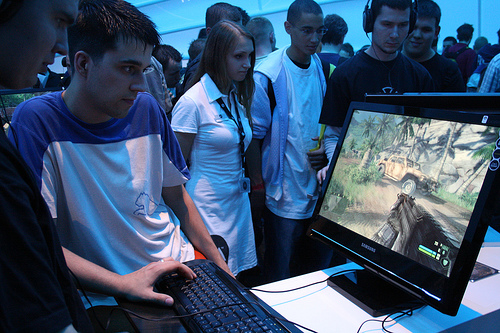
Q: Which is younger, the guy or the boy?
A: The boy is younger than the guy.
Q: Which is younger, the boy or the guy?
A: The boy is younger than the guy.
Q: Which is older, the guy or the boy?
A: The guy is older than the boy.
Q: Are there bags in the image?
A: No, there are no bags.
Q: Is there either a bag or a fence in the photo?
A: No, there are no bags or fences.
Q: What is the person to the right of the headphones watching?
A: The person is watching the computer monitor.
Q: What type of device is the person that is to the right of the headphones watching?
A: The person is watching the computer monitor.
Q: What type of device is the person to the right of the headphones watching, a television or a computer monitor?
A: The person is watching a computer monitor.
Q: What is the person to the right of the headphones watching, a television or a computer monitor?
A: The person is watching a computer monitor.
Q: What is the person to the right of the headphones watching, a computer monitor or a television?
A: The person is watching a computer monitor.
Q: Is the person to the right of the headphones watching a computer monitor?
A: Yes, the person is watching a computer monitor.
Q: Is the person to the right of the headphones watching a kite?
A: No, the person is watching a computer monitor.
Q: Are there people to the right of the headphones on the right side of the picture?
A: Yes, there is a person to the right of the headphones.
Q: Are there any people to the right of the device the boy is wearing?
A: Yes, there is a person to the right of the headphones.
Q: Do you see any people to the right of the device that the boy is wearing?
A: Yes, there is a person to the right of the headphones.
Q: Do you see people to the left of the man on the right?
A: Yes, there is a person to the left of the man.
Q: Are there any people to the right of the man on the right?
A: No, the person is to the left of the man.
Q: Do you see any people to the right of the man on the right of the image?
A: No, the person is to the left of the man.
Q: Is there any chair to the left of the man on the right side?
A: No, there is a person to the left of the man.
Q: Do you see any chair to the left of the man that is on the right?
A: No, there is a person to the left of the man.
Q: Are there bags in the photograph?
A: No, there are no bags.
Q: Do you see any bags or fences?
A: No, there are no bags or fences.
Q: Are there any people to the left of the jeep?
A: Yes, there are people to the left of the jeep.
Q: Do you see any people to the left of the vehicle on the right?
A: Yes, there are people to the left of the jeep.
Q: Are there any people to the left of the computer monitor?
A: Yes, there are people to the left of the computer monitor.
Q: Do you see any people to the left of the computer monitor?
A: Yes, there are people to the left of the computer monitor.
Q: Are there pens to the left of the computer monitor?
A: No, there are people to the left of the computer monitor.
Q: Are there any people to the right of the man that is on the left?
A: Yes, there are people to the right of the man.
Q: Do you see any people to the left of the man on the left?
A: No, the people are to the right of the man.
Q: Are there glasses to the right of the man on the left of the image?
A: No, there are people to the right of the man.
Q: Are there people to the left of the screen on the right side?
A: Yes, there are people to the left of the screen.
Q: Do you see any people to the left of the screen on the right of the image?
A: Yes, there are people to the left of the screen.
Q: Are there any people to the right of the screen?
A: No, the people are to the left of the screen.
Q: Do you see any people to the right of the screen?
A: No, the people are to the left of the screen.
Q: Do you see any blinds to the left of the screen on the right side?
A: No, there are people to the left of the screen.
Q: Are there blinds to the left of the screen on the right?
A: No, there are people to the left of the screen.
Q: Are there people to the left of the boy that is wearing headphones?
A: Yes, there are people to the left of the boy.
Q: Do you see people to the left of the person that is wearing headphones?
A: Yes, there are people to the left of the boy.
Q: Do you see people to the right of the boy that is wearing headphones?
A: No, the people are to the left of the boy.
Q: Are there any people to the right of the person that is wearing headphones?
A: No, the people are to the left of the boy.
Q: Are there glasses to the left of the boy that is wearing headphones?
A: No, there are people to the left of the boy.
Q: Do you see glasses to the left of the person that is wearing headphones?
A: No, there are people to the left of the boy.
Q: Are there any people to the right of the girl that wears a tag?
A: Yes, there are people to the right of the girl.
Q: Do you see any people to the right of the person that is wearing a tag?
A: Yes, there are people to the right of the girl.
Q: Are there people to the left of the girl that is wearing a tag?
A: No, the people are to the right of the girl.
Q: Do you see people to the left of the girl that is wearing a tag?
A: No, the people are to the right of the girl.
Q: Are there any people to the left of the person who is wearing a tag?
A: No, the people are to the right of the girl.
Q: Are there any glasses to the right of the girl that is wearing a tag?
A: No, there are people to the right of the girl.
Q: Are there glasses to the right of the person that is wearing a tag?
A: No, there are people to the right of the girl.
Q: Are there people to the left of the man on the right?
A: Yes, there are people to the left of the man.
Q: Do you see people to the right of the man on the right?
A: No, the people are to the left of the man.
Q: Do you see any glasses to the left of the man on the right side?
A: No, there are people to the left of the man.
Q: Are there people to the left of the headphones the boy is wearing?
A: Yes, there are people to the left of the headphones.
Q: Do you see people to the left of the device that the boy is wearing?
A: Yes, there are people to the left of the headphones.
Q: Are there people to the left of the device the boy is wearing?
A: Yes, there are people to the left of the headphones.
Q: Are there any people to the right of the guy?
A: Yes, there are people to the right of the guy.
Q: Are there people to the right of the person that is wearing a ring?
A: Yes, there are people to the right of the guy.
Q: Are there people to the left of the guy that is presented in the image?
A: No, the people are to the right of the guy.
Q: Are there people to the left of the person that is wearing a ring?
A: No, the people are to the right of the guy.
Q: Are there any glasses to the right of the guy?
A: No, there are people to the right of the guy.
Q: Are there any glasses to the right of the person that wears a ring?
A: No, there are people to the right of the guy.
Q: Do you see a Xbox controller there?
A: No, there are no Xbox controllers.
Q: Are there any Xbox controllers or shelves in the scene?
A: No, there are no Xbox controllers or shelves.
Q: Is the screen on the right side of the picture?
A: Yes, the screen is on the right of the image.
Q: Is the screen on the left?
A: No, the screen is on the right of the image.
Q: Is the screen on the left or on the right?
A: The screen is on the right of the image.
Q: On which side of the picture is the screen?
A: The screen is on the right of the image.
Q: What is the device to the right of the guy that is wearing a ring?
A: The device is a screen.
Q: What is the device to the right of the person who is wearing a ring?
A: The device is a screen.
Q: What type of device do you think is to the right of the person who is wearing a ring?
A: The device is a screen.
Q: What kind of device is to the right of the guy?
A: The device is a screen.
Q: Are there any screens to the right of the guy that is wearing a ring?
A: Yes, there is a screen to the right of the guy.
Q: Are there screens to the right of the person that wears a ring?
A: Yes, there is a screen to the right of the guy.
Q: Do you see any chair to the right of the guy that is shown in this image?
A: No, there is a screen to the right of the guy.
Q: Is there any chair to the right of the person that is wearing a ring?
A: No, there is a screen to the right of the guy.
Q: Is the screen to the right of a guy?
A: Yes, the screen is to the right of a guy.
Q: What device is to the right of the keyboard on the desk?
A: The device is a screen.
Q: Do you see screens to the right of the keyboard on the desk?
A: Yes, there is a screen to the right of the keyboard.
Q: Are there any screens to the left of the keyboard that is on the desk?
A: No, the screen is to the right of the keyboard.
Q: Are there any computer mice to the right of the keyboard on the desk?
A: No, there is a screen to the right of the keyboard.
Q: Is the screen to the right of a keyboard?
A: Yes, the screen is to the right of a keyboard.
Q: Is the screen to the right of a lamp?
A: No, the screen is to the right of a keyboard.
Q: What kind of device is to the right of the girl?
A: The device is a screen.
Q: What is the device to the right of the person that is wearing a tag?
A: The device is a screen.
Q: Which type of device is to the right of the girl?
A: The device is a screen.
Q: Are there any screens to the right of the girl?
A: Yes, there is a screen to the right of the girl.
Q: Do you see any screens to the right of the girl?
A: Yes, there is a screen to the right of the girl.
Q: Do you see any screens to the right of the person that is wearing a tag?
A: Yes, there is a screen to the right of the girl.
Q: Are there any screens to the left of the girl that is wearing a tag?
A: No, the screen is to the right of the girl.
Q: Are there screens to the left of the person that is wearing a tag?
A: No, the screen is to the right of the girl.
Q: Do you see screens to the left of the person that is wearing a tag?
A: No, the screen is to the right of the girl.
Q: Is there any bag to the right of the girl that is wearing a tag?
A: No, there is a screen to the right of the girl.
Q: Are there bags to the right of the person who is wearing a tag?
A: No, there is a screen to the right of the girl.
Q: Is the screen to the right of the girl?
A: Yes, the screen is to the right of the girl.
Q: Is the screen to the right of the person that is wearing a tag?
A: Yes, the screen is to the right of the girl.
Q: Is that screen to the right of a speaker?
A: No, the screen is to the right of the girl.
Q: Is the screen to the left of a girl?
A: No, the screen is to the right of a girl.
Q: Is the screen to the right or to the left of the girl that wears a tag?
A: The screen is to the right of the girl.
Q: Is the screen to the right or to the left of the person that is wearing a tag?
A: The screen is to the right of the girl.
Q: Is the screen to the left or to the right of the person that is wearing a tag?
A: The screen is to the right of the girl.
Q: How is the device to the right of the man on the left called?
A: The device is a screen.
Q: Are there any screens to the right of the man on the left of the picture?
A: Yes, there is a screen to the right of the man.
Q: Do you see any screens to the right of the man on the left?
A: Yes, there is a screen to the right of the man.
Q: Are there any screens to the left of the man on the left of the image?
A: No, the screen is to the right of the man.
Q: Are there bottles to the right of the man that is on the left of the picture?
A: No, there is a screen to the right of the man.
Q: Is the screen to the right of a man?
A: Yes, the screen is to the right of a man.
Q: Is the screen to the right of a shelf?
A: No, the screen is to the right of a man.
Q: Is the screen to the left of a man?
A: No, the screen is to the right of a man.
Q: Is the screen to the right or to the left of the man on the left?
A: The screen is to the right of the man.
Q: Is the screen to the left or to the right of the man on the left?
A: The screen is to the right of the man.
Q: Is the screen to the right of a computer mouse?
A: No, the screen is to the right of a keyboard.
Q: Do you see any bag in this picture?
A: No, there are no bags.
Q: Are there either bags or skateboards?
A: No, there are no bags or skateboards.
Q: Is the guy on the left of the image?
A: Yes, the guy is on the left of the image.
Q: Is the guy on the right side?
A: No, the guy is on the left of the image.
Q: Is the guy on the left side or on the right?
A: The guy is on the left of the image.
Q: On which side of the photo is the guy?
A: The guy is on the left of the image.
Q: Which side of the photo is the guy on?
A: The guy is on the left of the image.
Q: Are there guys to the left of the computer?
A: Yes, there is a guy to the left of the computer.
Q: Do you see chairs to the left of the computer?
A: No, there is a guy to the left of the computer.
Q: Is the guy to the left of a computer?
A: Yes, the guy is to the left of a computer.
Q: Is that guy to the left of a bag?
A: No, the guy is to the left of a computer.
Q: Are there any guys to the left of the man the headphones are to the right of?
A: Yes, there is a guy to the left of the man.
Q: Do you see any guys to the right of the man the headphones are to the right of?
A: No, the guy is to the left of the man.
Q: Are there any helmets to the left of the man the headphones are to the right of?
A: No, there is a guy to the left of the man.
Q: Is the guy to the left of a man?
A: Yes, the guy is to the left of a man.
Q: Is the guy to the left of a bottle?
A: No, the guy is to the left of a man.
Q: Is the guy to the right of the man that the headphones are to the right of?
A: No, the guy is to the left of the man.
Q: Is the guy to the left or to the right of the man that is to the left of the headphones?
A: The guy is to the left of the man.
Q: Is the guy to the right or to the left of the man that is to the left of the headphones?
A: The guy is to the left of the man.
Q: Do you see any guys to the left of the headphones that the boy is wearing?
A: Yes, there is a guy to the left of the headphones.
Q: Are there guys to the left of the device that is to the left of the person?
A: Yes, there is a guy to the left of the headphones.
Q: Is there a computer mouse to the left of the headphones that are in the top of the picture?
A: No, there is a guy to the left of the headphones.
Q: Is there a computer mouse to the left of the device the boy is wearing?
A: No, there is a guy to the left of the headphones.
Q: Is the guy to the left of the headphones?
A: Yes, the guy is to the left of the headphones.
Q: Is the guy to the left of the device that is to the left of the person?
A: Yes, the guy is to the left of the headphones.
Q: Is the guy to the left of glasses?
A: No, the guy is to the left of the headphones.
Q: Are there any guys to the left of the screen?
A: Yes, there is a guy to the left of the screen.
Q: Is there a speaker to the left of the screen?
A: No, there is a guy to the left of the screen.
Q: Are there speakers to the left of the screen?
A: No, there is a guy to the left of the screen.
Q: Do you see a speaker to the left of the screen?
A: No, there is a guy to the left of the screen.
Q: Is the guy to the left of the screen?
A: Yes, the guy is to the left of the screen.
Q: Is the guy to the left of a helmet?
A: No, the guy is to the left of the screen.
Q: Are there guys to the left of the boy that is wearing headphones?
A: Yes, there is a guy to the left of the boy.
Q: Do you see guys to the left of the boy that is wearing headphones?
A: Yes, there is a guy to the left of the boy.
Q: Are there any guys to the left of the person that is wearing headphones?
A: Yes, there is a guy to the left of the boy.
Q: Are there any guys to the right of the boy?
A: No, the guy is to the left of the boy.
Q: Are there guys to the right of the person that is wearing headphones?
A: No, the guy is to the left of the boy.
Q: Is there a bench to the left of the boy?
A: No, there is a guy to the left of the boy.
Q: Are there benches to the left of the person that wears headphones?
A: No, there is a guy to the left of the boy.